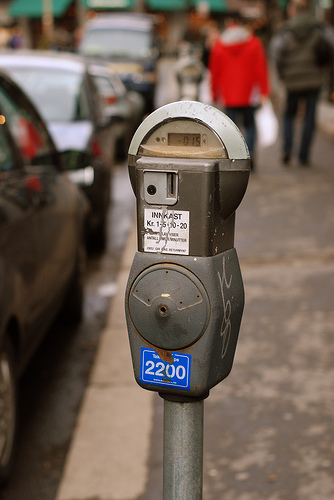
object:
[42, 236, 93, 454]
road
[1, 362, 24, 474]
rim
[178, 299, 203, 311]
line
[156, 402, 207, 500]
metal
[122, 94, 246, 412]
parking meter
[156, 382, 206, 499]
pole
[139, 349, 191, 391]
sticker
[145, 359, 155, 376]
number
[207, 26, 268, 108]
jacket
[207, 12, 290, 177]
person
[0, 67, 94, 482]
car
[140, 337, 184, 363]
rust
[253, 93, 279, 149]
bag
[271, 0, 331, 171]
pedestrians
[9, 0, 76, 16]
awning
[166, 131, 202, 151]
screen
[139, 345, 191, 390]
sign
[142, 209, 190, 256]
sign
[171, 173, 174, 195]
coin slot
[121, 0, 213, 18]
patio cover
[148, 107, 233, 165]
sign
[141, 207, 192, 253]
sticker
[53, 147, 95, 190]
mirror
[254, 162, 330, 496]
part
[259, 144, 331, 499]
walkpath